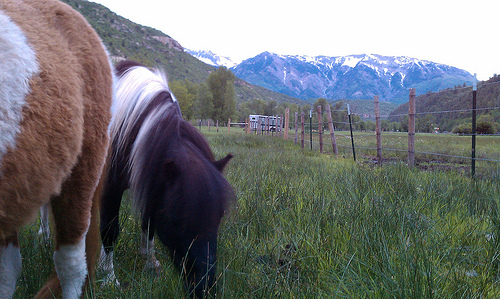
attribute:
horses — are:
[1, 49, 290, 290]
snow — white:
[247, 50, 476, 102]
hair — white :
[104, 58, 179, 240]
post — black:
[470, 72, 477, 175]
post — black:
[405, 85, 416, 169]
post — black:
[371, 96, 385, 163]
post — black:
[322, 102, 337, 154]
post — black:
[282, 104, 288, 141]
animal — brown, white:
[3, 2, 118, 294]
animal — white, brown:
[103, 53, 235, 297]